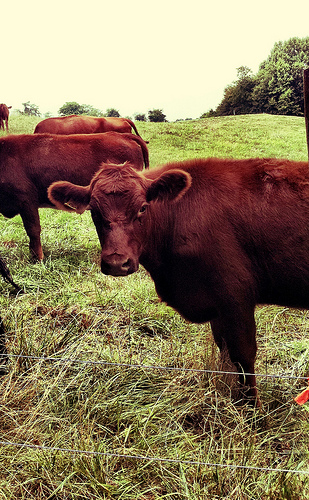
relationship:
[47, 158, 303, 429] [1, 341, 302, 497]
cow standing next to fence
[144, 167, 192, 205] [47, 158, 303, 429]
ear on cow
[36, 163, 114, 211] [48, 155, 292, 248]
ear on cow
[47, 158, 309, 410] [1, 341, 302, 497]
cow are near fence